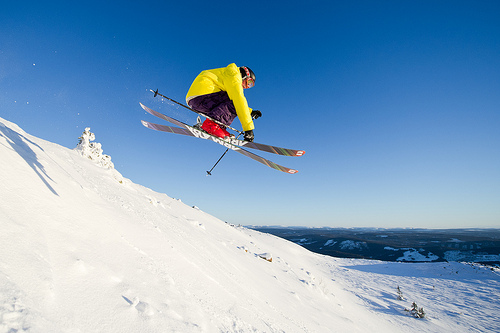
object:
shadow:
[0, 120, 59, 197]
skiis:
[137, 100, 300, 176]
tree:
[402, 299, 427, 320]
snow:
[0, 114, 499, 333]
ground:
[328, 256, 500, 333]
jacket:
[183, 62, 255, 131]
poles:
[204, 114, 258, 178]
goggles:
[238, 65, 256, 90]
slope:
[0, 115, 416, 332]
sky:
[0, 0, 499, 230]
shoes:
[198, 117, 226, 140]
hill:
[0, 117, 457, 332]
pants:
[185, 89, 237, 126]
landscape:
[0, 0, 499, 333]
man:
[184, 61, 262, 142]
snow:
[4, 127, 461, 327]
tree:
[69, 126, 115, 171]